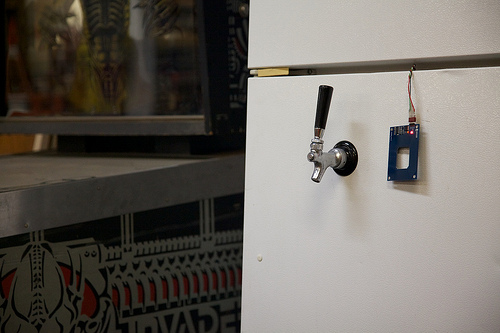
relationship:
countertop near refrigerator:
[0, 149, 243, 242] [240, 2, 497, 330]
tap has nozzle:
[305, 84, 356, 181] [311, 167, 321, 184]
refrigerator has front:
[240, 2, 497, 330] [238, 1, 498, 327]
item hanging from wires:
[389, 123, 418, 182] [408, 66, 415, 121]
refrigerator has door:
[240, 2, 497, 330] [241, 65, 498, 326]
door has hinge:
[241, 65, 498, 326] [250, 65, 311, 78]